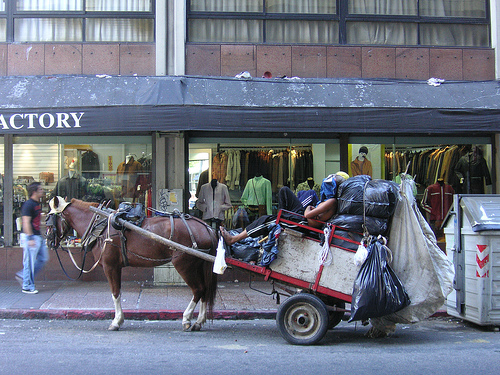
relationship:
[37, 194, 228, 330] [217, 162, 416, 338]
horse carrying wheelbarrow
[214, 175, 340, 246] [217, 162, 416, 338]
man sleeping on wheelbarrow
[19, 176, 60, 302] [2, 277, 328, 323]
man walking on sidewalk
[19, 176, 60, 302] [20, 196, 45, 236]
man wearing t-shirt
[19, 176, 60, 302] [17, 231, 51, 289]
man wearing jeans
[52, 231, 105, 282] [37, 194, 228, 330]
reins of horse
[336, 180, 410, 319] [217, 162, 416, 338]
bags on wheelbarrow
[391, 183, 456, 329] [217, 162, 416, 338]
bag on wheelbarrow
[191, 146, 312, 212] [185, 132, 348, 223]
clothes in window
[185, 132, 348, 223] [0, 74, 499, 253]
window of shop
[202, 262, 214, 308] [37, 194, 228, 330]
tail of horse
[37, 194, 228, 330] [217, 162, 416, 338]
horse pulling cart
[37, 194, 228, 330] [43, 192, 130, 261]
horse wearing gear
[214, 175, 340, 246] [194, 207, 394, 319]
man resting in cart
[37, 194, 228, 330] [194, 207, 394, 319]
horse pulling cart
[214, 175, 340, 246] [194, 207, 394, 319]
man resting on cart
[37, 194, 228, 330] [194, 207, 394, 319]
horse pulled cart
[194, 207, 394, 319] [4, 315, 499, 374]
cart on road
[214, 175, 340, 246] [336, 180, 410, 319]
man resting on bags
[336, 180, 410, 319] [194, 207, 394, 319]
bags stacked on cart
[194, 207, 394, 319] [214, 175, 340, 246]
cart with man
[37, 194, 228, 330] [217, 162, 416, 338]
horse and buggy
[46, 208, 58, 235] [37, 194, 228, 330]
blinders of horse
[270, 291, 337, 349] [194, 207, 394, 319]
wheel on cart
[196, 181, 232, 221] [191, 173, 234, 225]
clothes on manequin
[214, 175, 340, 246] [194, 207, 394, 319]
man snoozing on cart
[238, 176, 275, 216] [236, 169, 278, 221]
shirt on manequin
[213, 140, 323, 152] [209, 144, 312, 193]
rack of jackets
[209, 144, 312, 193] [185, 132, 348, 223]
jackets in window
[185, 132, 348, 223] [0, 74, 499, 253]
window of store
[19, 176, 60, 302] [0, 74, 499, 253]
man walking by store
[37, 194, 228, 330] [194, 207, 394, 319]
horse attached to cart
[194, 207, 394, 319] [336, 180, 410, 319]
cart filled with bags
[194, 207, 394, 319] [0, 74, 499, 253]
cart in front of business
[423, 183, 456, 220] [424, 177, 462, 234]
jacket on manequin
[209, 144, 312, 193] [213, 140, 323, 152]
jackets on rack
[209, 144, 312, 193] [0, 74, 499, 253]
jackets inside store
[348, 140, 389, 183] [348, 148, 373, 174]
poster with man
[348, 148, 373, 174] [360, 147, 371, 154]
man wearing hat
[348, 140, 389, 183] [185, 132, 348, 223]
poster on window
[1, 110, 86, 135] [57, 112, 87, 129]
name in letters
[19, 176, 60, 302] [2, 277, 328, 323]
man standing on sidewalk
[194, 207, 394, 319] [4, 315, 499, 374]
cart parked on street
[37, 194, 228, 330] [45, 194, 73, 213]
horse wearing hat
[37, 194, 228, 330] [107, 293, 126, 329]
horse has white sox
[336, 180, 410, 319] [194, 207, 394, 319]
bags on cart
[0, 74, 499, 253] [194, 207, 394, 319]
business next to cart